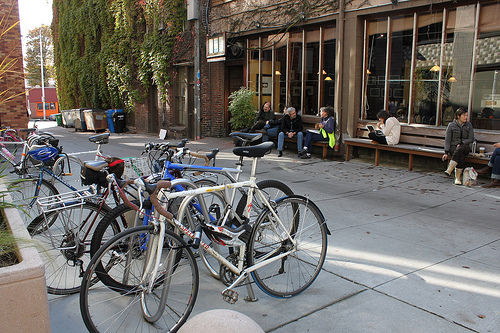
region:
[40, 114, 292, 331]
Bikes on the sidewalk.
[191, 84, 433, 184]
people sitting on a bench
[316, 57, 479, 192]
Bench against the building.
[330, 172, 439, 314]
Crack on the sidewalk.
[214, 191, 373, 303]
Wheel on the bike.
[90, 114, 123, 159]
Seat on the bike.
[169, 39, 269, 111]
Door on the building.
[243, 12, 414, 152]
Windows on the building.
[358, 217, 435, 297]
Sunlight on the sidewalk.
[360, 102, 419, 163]
Woman on the bench.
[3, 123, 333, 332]
a line of bikes in the racks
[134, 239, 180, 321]
the bike rack behind the spokes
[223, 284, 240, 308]
the metal bike pedal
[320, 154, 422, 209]
leaves by the bench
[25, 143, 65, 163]
a blue helmet hanging on the handle bars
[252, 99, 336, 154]
the people on the bench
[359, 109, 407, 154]
the women seated crosslegged on the bench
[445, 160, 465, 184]
the white boots on the womens feet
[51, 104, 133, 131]
A line of mutliple trash cans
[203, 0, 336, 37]
Vvines growing on the building above the window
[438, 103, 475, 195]
person sitting on bench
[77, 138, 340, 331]
black and white bicycle with tan handles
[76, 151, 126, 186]
red bag attached to bicycle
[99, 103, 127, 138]
blue trashcan on sidewalk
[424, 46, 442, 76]
ceiling light inside store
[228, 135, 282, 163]
black , curved, bicycle seat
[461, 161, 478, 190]
bag with handles next to person on bench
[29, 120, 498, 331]
stone cement paved sidewalk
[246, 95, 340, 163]
three people sitting on bench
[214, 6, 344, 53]
black wires on top of store front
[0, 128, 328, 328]
multiple bikes parked on the sidewalk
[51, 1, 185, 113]
green vines growing on the building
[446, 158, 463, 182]
woman is wearing tall boots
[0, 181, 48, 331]
concrete planter on sidewalk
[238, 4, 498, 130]
glass windows on side of the building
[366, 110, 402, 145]
woman is working on her laptop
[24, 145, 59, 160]
blue bike helmet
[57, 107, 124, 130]
trashcans on the sidewalk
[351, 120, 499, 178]
wooden bench is being used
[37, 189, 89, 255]
bike rack for storage on the bike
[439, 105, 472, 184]
Woman wearing gray coat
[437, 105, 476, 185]
Woman wearing tan boots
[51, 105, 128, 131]
Row of trash cans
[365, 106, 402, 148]
Woman sitting cross-legged with laptop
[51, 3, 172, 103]
Ivy growing up a wall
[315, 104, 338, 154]
Person with bright green sweater tied around waist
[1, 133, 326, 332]
Grouping of several bicycles parked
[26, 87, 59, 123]
Red and orange building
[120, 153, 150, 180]
Empty wire basket on bicycle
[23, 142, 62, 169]
Blue helmet perched on bicycle